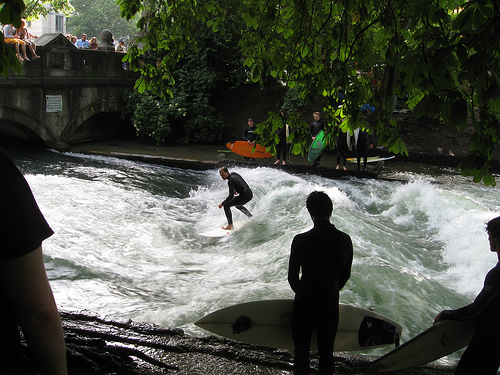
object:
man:
[213, 165, 256, 230]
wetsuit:
[223, 172, 253, 223]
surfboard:
[224, 138, 276, 159]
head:
[219, 168, 229, 180]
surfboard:
[198, 217, 250, 238]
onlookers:
[0, 19, 27, 64]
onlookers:
[89, 37, 98, 50]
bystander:
[0, 135, 68, 374]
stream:
[5, 166, 500, 338]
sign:
[44, 93, 65, 113]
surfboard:
[307, 126, 336, 163]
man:
[285, 190, 354, 373]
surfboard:
[193, 297, 402, 352]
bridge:
[0, 32, 145, 149]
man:
[244, 116, 259, 163]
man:
[309, 110, 324, 169]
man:
[333, 115, 349, 171]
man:
[352, 120, 371, 174]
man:
[433, 216, 500, 375]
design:
[231, 313, 265, 336]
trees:
[134, 1, 499, 169]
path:
[105, 123, 498, 174]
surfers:
[269, 107, 295, 167]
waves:
[211, 169, 384, 349]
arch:
[0, 107, 58, 149]